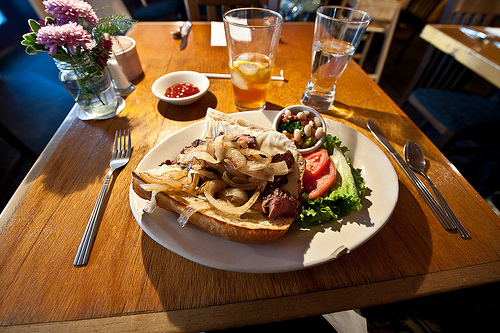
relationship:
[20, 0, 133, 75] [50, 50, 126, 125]
flowers are in vase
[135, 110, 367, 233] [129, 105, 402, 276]
food on a plate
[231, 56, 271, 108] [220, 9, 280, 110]
liquid in a glass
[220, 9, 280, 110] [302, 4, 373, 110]
glass has water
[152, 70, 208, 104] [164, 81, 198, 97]
bowl has ketchup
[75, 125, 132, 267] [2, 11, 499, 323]
fork on table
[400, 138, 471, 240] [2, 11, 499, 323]
spoon on table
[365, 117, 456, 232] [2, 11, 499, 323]
knife on table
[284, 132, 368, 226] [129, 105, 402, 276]
lettuce on plate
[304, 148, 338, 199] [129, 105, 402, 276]
tomatoes on plate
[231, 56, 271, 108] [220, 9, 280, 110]
liquid in glass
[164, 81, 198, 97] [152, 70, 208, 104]
ketchup in bowl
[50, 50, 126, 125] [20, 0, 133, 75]
vase has flowers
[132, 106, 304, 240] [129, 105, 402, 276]
sandwich on a plate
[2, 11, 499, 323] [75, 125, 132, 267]
table has a fork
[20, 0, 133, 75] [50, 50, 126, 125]
flowers in vase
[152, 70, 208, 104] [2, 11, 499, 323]
bowl on table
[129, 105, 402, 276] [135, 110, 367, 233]
plate of food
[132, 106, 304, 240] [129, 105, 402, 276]
sandwich on plate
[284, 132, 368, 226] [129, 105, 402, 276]
lettuce on a plate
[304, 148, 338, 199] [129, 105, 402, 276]
tomatoes on a plate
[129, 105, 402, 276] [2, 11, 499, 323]
silverware on a table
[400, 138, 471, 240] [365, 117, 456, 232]
spoon with knife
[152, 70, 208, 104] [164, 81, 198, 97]
bowl of ketchup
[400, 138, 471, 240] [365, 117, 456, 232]
spoon and knife